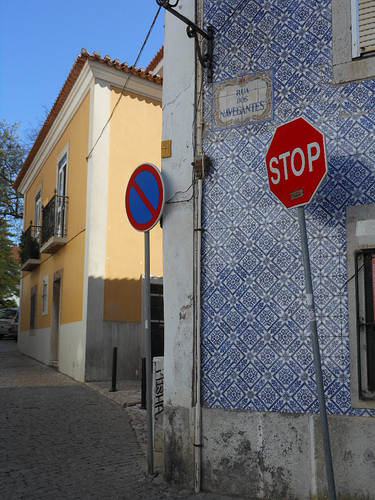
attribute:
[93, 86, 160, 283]
wall — yellow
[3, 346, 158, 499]
street — gray, cobblestone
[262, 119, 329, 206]
sign — red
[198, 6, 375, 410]
wall — blue, colorful, tiled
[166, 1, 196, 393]
wall — white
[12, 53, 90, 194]
gutter — orange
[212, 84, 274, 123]
sign — blue, white, french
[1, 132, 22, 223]
leaves — green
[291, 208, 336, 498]
pole — tall, metal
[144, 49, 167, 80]
roof — clay, tiled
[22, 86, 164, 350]
building — yellow, white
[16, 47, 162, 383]
house — yellow, white, painted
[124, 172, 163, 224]
sign — red, blue, circular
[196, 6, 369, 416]
tiles — blue, white, decorative, geometric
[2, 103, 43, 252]
tree — tall, green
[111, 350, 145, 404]
poles — black, metal